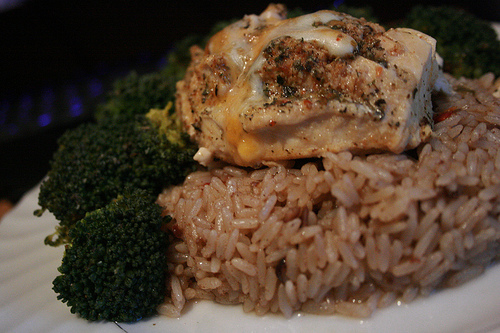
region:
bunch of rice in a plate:
[164, 74, 494, 316]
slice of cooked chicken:
[176, 9, 442, 154]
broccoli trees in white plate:
[43, 54, 190, 325]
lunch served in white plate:
[38, 10, 498, 321]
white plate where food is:
[2, 145, 498, 330]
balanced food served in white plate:
[20, 0, 497, 326]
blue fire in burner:
[1, 64, 106, 139]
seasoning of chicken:
[248, 8, 383, 116]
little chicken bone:
[191, 143, 211, 167]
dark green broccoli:
[42, 49, 192, 320]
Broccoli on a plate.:
[32, 116, 169, 330]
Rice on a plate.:
[179, 180, 496, 312]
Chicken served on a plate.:
[193, 10, 470, 155]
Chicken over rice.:
[168, 0, 498, 330]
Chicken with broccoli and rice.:
[27, 13, 407, 200]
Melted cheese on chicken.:
[211, 9, 313, 169]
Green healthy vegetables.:
[63, 169, 224, 330]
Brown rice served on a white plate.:
[193, 164, 457, 319]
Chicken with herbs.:
[175, 9, 472, 179]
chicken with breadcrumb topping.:
[175, 6, 471, 173]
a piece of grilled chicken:
[178, 14, 432, 159]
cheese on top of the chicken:
[205, 10, 356, 153]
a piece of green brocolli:
[52, 199, 177, 318]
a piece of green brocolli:
[45, 124, 183, 221]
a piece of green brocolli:
[102, 56, 182, 123]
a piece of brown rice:
[258, 191, 280, 223]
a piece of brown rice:
[256, 246, 268, 285]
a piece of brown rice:
[335, 203, 350, 237]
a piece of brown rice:
[380, 228, 391, 270]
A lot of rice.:
[156, 72, 495, 310]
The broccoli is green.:
[39, 1, 499, 324]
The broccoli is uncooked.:
[38, 2, 497, 319]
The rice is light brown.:
[151, 68, 498, 315]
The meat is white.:
[173, 3, 455, 165]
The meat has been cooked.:
[171, 1, 452, 165]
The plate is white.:
[0, 171, 499, 331]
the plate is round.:
[0, 169, 497, 328]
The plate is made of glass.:
[1, 169, 499, 329]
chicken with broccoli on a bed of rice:
[22, 1, 497, 312]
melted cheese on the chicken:
[193, 9, 371, 105]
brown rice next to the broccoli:
[189, 169, 480, 296]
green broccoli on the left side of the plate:
[41, 25, 188, 325]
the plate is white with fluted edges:
[4, 187, 56, 329]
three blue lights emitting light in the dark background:
[25, 65, 105, 128]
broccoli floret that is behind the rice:
[433, 12, 495, 79]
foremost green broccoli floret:
[53, 209, 200, 318]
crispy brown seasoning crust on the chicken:
[254, 34, 385, 124]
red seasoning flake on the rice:
[435, 106, 462, 129]